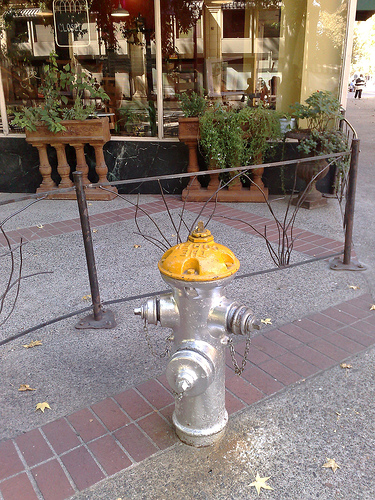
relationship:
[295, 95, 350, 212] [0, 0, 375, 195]
planter near building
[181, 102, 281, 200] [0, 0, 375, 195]
planter near building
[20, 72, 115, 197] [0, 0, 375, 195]
planter near building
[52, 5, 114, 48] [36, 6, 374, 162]
sign in window of store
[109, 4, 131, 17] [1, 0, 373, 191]
hanging light from ceiling inside store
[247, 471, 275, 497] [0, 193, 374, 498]
leaf laying on ground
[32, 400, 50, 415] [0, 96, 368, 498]
leaf on ground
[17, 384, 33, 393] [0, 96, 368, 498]
leaf on ground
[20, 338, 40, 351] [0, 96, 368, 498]
leaf on ground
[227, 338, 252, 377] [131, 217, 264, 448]
chain on fire hydrant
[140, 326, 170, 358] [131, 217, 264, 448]
chain on fire hydrant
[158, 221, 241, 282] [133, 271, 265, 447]
cover on hydrant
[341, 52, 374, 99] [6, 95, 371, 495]
person on street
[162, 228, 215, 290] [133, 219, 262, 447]
cover on hydrant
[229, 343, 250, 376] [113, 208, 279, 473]
chain on fire hydrant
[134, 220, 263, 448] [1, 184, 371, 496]
fire hydrant on sidewalk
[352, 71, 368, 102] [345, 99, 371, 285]
person on street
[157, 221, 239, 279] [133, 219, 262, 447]
top of hydrant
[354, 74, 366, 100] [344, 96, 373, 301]
person on sidewalk